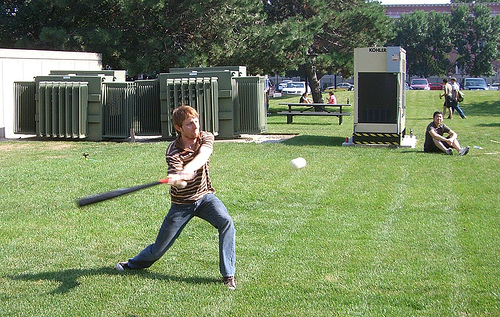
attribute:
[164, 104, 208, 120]
hair — red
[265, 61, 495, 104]
cars — parked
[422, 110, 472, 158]
man sitting — sitting down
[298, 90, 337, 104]
people — sitting 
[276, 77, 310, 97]
car — white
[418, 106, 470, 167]
man — watching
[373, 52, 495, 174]
people — walking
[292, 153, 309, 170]
baseball — White,  air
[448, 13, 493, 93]
tree — large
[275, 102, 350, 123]
picnic table — dark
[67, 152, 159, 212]
bat — blurred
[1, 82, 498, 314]
grass — green, thick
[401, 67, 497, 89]
car — red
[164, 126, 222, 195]
shirt — striped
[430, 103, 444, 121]
hair — black